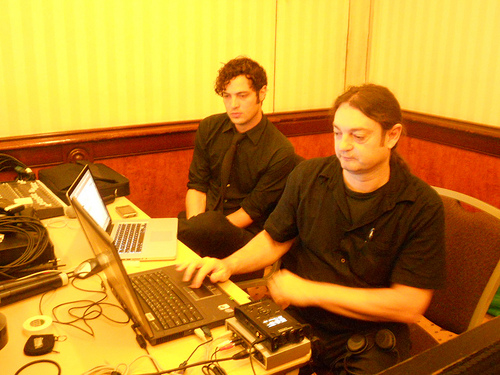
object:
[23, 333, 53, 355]
purse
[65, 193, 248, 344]
laptop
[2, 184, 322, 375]
desk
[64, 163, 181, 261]
laptop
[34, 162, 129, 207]
laptop bag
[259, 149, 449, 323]
shirt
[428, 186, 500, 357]
chair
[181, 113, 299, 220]
shirt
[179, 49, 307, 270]
man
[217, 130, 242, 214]
tie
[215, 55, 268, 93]
hair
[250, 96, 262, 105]
burn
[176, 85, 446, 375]
man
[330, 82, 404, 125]
hair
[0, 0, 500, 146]
wall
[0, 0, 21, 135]
stripes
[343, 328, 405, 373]
headphones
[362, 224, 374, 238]
pen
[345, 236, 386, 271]
pocket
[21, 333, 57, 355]
coin purse